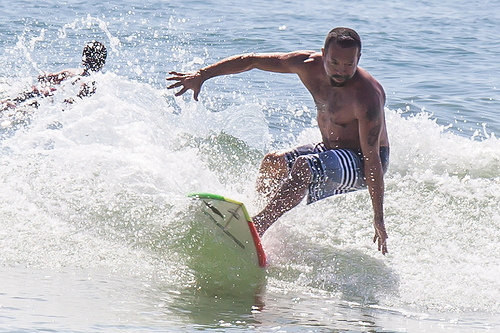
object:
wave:
[0, 13, 500, 324]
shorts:
[277, 142, 389, 204]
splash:
[0, 18, 500, 311]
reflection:
[6, 153, 398, 333]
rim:
[247, 217, 268, 264]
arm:
[167, 50, 312, 101]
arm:
[357, 90, 388, 256]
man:
[167, 26, 390, 256]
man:
[0, 41, 107, 114]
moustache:
[329, 73, 350, 88]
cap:
[17, 71, 498, 231]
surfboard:
[186, 192, 269, 284]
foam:
[0, 14, 499, 318]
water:
[1, 0, 498, 332]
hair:
[324, 27, 362, 63]